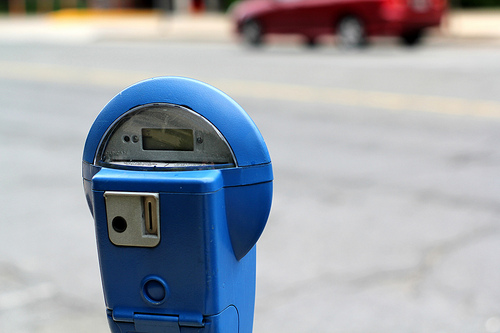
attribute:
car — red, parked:
[231, 0, 445, 47]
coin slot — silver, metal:
[141, 195, 158, 236]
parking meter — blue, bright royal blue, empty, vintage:
[82, 74, 274, 332]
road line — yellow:
[277, 79, 499, 116]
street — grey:
[1, 38, 500, 331]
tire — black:
[336, 15, 367, 46]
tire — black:
[236, 20, 263, 42]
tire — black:
[400, 27, 423, 44]